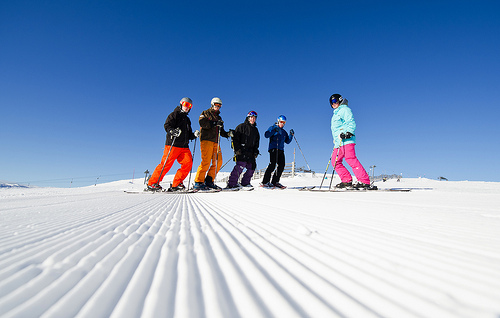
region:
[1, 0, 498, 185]
a beautiful clear blue sky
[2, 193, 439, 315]
straight lines in the snow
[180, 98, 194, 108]
orange ski goggles on a person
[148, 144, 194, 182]
reddish orange pants on a person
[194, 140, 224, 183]
yellow pants on a person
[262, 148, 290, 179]
black pants on a person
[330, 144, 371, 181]
pink pants on a person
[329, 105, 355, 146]
a light blue coat on a person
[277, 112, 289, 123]
a blue helmet on a person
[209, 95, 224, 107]
a white helmet on a person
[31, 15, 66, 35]
white clouds in blue sky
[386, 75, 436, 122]
white clouds in blue sky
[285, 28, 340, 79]
white clouds in blue sky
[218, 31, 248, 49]
white clouds in blue sky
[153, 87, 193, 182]
skier in white snow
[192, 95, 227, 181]
skier in white snow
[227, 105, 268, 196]
skier in white snow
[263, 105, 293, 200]
skier in white snow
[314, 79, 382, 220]
skier in white snow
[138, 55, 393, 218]
five people are skiing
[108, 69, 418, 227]
a group of skiers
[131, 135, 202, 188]
his pants are bright orange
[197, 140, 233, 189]
his pants are orange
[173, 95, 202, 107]
his goggles are orange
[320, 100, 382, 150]
her jacket is light blue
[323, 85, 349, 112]
her helmet is black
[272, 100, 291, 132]
his helmet is blue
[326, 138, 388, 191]
pink ski pants on woman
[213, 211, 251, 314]
tracks in white snow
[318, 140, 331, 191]
metal ski pole held by woman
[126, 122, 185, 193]
bright orange ski pants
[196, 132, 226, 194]
light orange ski pants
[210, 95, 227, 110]
white helmet on skier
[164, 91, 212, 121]
orange goggles on skier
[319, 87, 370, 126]
black helmet on skier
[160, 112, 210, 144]
black jacket on skier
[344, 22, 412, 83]
deep blue sky in upper right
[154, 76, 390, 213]
These people are skiing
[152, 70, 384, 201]
There are 5 people skiing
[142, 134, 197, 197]
This person has red ski pants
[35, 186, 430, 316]
Tracks in the snow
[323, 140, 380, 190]
Hot pink snow pants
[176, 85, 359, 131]
Skiers are wearing helmets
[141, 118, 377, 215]
Skiers are holding ski poles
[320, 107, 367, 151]
Baby blue snow jacket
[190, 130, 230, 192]
Skier is wearing orange ski pants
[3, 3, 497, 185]
Sky is clear and blue